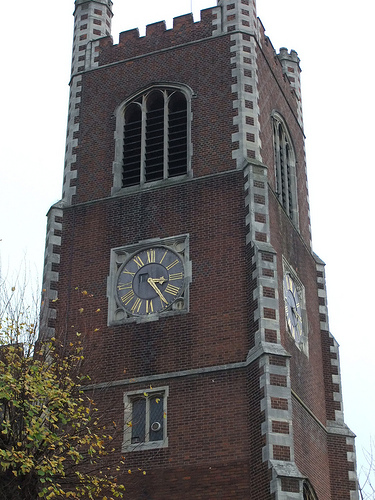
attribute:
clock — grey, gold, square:
[108, 231, 192, 329]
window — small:
[118, 386, 170, 454]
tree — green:
[3, 255, 144, 500]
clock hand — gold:
[148, 275, 169, 286]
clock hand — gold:
[149, 283, 168, 306]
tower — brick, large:
[55, 1, 319, 211]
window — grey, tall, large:
[112, 80, 196, 198]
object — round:
[151, 423, 163, 433]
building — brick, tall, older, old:
[38, 2, 356, 499]